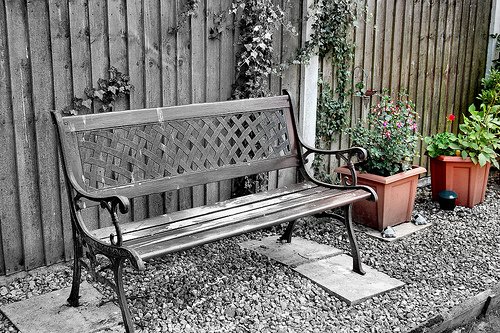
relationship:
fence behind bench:
[3, 2, 300, 104] [38, 73, 388, 333]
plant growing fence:
[208, 0, 363, 187] [1, 2, 499, 278]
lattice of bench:
[76, 106, 293, 196] [38, 73, 388, 333]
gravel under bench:
[185, 274, 335, 315] [41, 88, 385, 307]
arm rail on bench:
[287, 97, 375, 190] [38, 73, 388, 333]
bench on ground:
[38, 73, 388, 333] [2, 157, 499, 333]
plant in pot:
[422, 93, 498, 174] [444, 146, 471, 203]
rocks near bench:
[187, 268, 473, 328] [38, 73, 388, 333]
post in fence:
[284, 58, 338, 201] [401, 14, 448, 85]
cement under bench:
[269, 243, 406, 308] [41, 88, 385, 307]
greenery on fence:
[303, 12, 400, 150] [283, 3, 466, 139]